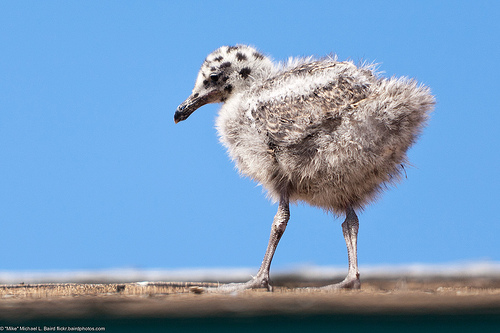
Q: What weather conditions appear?
A: It is clear.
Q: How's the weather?
A: It is clear.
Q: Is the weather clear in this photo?
A: Yes, it is clear.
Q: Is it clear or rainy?
A: It is clear.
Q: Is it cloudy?
A: No, it is clear.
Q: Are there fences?
A: No, there are no fences.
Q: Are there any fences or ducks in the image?
A: No, there are no fences or ducks.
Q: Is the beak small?
A: Yes, the beak is small.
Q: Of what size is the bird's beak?
A: The beak is small.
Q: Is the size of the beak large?
A: No, the beak is small.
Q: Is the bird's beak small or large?
A: The beak is small.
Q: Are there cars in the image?
A: No, there are no cars.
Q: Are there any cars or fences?
A: No, there are no cars or fences.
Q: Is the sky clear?
A: Yes, the sky is clear.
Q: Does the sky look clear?
A: Yes, the sky is clear.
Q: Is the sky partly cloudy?
A: No, the sky is clear.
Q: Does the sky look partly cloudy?
A: No, the sky is clear.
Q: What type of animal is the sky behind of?
A: The sky is behind the bird.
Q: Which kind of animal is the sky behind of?
A: The sky is behind the bird.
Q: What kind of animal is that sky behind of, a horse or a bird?
A: The sky is behind a bird.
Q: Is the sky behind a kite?
A: No, the sky is behind a bird.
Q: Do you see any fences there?
A: No, there are no fences.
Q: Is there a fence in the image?
A: No, there are no fences.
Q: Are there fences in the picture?
A: No, there are no fences.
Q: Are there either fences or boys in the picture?
A: No, there are no fences or boys.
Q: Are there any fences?
A: No, there are no fences.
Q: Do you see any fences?
A: No, there are no fences.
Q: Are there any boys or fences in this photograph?
A: No, there are no fences or boys.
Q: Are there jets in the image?
A: No, there are no jets.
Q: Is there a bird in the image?
A: Yes, there is a bird.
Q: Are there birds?
A: Yes, there is a bird.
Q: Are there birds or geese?
A: Yes, there is a bird.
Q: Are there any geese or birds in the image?
A: Yes, there is a bird.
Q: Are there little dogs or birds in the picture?
A: Yes, there is a little bird.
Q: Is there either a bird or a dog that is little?
A: Yes, the bird is little.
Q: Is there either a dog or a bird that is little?
A: Yes, the bird is little.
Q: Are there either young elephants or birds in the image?
A: Yes, there is a young bird.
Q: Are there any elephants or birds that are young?
A: Yes, the bird is young.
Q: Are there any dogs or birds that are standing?
A: Yes, the bird is standing.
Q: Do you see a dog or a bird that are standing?
A: Yes, the bird is standing.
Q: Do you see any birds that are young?
A: Yes, there is a young bird.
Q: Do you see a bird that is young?
A: Yes, there is a bird that is young.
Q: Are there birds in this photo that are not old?
A: Yes, there is an young bird.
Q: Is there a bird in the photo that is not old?
A: Yes, there is an young bird.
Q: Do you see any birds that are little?
A: Yes, there is a little bird.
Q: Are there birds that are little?
A: Yes, there is a bird that is little.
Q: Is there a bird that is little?
A: Yes, there is a bird that is little.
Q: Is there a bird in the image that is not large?
A: Yes, there is a little bird.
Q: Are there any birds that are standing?
A: Yes, there is a bird that is standing.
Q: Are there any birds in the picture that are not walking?
A: Yes, there is a bird that is standing.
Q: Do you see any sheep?
A: No, there are no sheep.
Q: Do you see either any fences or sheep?
A: No, there are no sheep or fences.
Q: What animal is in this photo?
A: The animal is a bird.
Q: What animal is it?
A: The animal is a bird.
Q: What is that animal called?
A: This is a bird.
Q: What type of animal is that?
A: This is a bird.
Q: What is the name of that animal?
A: This is a bird.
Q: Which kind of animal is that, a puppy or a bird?
A: This is a bird.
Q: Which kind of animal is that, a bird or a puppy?
A: This is a bird.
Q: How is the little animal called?
A: The animal is a bird.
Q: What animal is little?
A: The animal is a bird.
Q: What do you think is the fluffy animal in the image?
A: The animal is a bird.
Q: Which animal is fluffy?
A: The animal is a bird.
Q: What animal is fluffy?
A: The animal is a bird.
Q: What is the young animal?
A: The animal is a bird.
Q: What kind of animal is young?
A: The animal is a bird.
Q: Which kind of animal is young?
A: The animal is a bird.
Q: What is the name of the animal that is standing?
A: The animal is a bird.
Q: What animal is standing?
A: The animal is a bird.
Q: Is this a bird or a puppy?
A: This is a bird.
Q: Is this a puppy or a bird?
A: This is a bird.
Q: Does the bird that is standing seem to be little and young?
A: Yes, the bird is little and young.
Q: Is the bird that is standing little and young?
A: Yes, the bird is little and young.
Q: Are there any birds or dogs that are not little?
A: No, there is a bird but it is little.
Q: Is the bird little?
A: Yes, the bird is little.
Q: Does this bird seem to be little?
A: Yes, the bird is little.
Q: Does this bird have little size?
A: Yes, the bird is little.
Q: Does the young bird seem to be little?
A: Yes, the bird is little.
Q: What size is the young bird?
A: The bird is little.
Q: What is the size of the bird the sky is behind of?
A: The bird is little.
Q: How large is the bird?
A: The bird is little.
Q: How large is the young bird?
A: The bird is little.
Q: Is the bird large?
A: No, the bird is little.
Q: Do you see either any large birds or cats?
A: No, there is a bird but it is little.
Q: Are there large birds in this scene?
A: No, there is a bird but it is little.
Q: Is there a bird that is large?
A: No, there is a bird but it is little.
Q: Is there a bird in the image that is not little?
A: No, there is a bird but it is little.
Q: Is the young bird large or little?
A: The bird is little.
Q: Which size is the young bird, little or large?
A: The bird is little.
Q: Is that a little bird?
A: Yes, that is a little bird.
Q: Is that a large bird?
A: No, that is a little bird.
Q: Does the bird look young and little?
A: Yes, the bird is young and little.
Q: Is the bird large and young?
A: No, the bird is young but little.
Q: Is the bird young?
A: Yes, the bird is young.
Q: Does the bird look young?
A: Yes, the bird is young.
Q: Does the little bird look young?
A: Yes, the bird is young.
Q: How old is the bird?
A: The bird is young.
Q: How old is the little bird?
A: The bird is young.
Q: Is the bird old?
A: No, the bird is young.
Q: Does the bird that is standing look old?
A: No, the bird is young.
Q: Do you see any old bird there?
A: No, there is a bird but it is young.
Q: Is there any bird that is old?
A: No, there is a bird but it is young.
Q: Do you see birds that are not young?
A: No, there is a bird but it is young.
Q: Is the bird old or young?
A: The bird is young.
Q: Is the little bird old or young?
A: The bird is young.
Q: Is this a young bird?
A: Yes, this is a young bird.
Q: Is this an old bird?
A: No, this is a young bird.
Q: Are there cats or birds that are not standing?
A: No, there is a bird but it is standing.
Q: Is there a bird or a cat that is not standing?
A: No, there is a bird but it is standing.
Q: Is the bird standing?
A: Yes, the bird is standing.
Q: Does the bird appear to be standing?
A: Yes, the bird is standing.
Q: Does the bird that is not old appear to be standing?
A: Yes, the bird is standing.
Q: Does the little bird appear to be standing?
A: Yes, the bird is standing.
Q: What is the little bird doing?
A: The bird is standing.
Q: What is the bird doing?
A: The bird is standing.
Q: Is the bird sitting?
A: No, the bird is standing.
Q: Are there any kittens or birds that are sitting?
A: No, there is a bird but it is standing.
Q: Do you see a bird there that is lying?
A: No, there is a bird but it is standing.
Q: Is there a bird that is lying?
A: No, there is a bird but it is standing.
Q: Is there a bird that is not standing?
A: No, there is a bird but it is standing.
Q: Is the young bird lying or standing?
A: The bird is standing.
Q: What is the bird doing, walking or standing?
A: The bird is standing.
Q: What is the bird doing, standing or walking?
A: The bird is standing.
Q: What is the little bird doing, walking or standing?
A: The bird is standing.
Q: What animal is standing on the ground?
A: The bird is standing on the ground.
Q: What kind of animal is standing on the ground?
A: The animal is a bird.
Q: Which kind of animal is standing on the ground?
A: The animal is a bird.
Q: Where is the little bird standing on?
A: The bird is standing on the ground.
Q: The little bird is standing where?
A: The bird is standing on the ground.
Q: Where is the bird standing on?
A: The bird is standing on the ground.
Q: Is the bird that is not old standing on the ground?
A: Yes, the bird is standing on the ground.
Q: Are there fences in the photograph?
A: No, there are no fences.